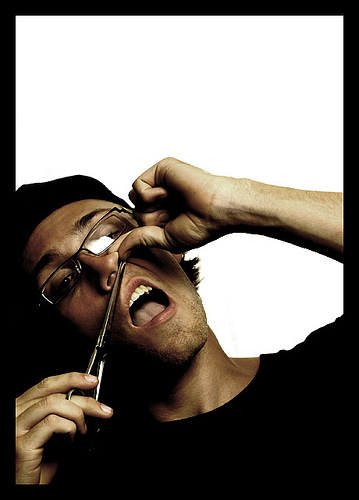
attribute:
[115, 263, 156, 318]
mouth — open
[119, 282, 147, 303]
teeth — upper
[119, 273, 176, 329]
mouth — open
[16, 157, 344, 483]
man — wearing black hat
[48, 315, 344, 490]
shirt — black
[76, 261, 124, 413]
scissors — hair trimming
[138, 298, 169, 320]
tongue — pink  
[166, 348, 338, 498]
shirt — black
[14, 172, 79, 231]
beret — black